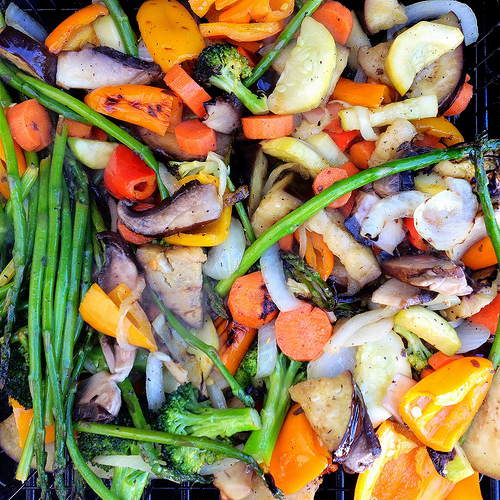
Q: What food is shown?
A: Stir fry.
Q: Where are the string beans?
A: By the carrots.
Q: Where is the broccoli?
A: In the stir fry.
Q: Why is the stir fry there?
A: To cook.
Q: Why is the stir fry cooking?
A: To eat.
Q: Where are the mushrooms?
A: In the stir fry.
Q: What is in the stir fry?
A: Vegetables.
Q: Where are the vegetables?
A: In the stir fry.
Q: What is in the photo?
A: Food.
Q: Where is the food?
A: In a group.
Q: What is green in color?
A: The food.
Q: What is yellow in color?
A: The food.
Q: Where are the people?
A: None in photo.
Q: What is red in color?
A: The food.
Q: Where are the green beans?
A: In the food.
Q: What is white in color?
A: The onion.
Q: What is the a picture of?
A: Stir fry.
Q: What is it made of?
A: Vegetables.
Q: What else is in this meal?
A: Fish.